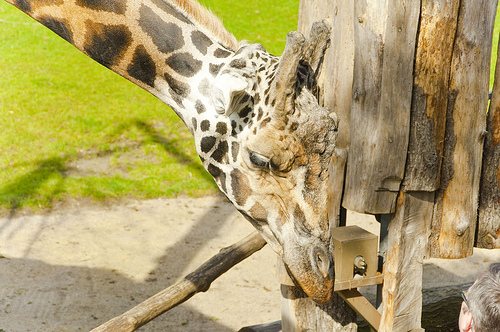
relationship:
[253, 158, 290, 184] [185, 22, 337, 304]
eye of giraffe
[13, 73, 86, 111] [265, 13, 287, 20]
grass on ground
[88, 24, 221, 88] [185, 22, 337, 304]
neck of giraffe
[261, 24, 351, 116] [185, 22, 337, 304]
ears of giraffe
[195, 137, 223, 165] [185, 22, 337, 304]
spots on giraffe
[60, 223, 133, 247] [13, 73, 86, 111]
sand in grass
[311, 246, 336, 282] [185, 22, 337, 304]
nostril of giraffe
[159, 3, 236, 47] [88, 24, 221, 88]
mane on neck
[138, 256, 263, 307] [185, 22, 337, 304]
stick under giraffe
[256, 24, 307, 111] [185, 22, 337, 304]
horns on giraffe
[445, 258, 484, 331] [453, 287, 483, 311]
man wearing glasses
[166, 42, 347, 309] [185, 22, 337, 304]
head of giraffe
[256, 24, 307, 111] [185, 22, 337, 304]
horns of giraffe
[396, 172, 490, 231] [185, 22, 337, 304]
fence near giraffe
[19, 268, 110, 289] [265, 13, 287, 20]
shadow on ground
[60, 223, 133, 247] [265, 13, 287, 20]
sand on ground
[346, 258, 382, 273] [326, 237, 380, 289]
bolt on lock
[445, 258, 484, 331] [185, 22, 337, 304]
man looking at giraffe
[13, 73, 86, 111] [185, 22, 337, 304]
grass next to giraffe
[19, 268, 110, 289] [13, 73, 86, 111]
shadow on grass